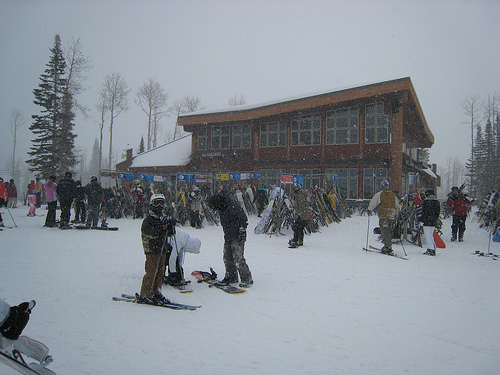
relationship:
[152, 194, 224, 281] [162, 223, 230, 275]
person in jacket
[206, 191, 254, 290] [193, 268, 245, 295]
person stepping on snowboard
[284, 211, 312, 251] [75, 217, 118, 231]
person riding snowboard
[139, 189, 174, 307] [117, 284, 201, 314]
boy on skis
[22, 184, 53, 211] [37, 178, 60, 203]
person wearing jacket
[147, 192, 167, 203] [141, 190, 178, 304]
helmet on head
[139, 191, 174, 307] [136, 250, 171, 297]
boy wearing pants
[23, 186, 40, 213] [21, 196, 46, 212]
child in snow gear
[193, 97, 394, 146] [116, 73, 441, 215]
windows on ski lodge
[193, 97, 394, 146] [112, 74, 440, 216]
windows on building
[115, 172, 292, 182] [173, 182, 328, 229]
banners near ski rack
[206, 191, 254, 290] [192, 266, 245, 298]
person strapping into snowboard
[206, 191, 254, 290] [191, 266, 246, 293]
person getting on snowboard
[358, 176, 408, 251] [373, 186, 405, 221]
person wearing brown jacket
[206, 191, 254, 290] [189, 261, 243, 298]
person on snowboard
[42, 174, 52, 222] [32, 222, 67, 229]
person on snowboard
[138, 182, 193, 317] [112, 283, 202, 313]
person on skis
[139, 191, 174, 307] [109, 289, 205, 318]
boy on skis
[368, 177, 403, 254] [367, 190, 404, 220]
person wearing jacket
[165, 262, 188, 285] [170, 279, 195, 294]
boot on snowboard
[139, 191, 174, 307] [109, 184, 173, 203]
boy wearing helmet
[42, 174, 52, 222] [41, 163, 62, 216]
person wearing jacket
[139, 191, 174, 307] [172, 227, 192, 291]
boy has pole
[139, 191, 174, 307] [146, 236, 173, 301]
boy has pole